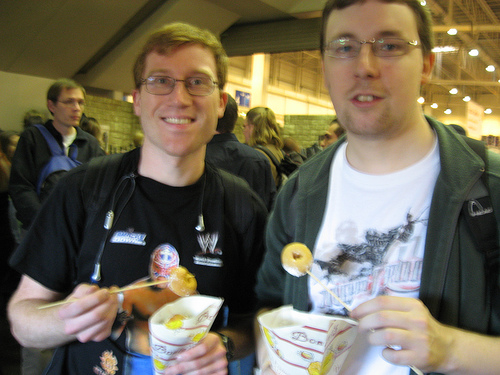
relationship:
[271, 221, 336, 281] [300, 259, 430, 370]
treat on stick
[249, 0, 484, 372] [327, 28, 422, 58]
man wearing eyeglasses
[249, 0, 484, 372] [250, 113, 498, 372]
man wearing jacket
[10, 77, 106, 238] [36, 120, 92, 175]
man carrying backpack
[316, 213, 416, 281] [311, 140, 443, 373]
design on shirt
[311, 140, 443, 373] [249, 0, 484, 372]
shirt on man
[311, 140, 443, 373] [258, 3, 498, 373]
shirt on man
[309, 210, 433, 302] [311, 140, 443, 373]
design on shirt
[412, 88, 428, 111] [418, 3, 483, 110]
light on ceiling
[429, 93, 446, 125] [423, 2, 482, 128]
light on ceiling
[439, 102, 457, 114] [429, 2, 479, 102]
light on ceiling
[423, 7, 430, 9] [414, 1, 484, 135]
light on ceiling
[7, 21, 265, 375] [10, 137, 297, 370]
boys wearing shirt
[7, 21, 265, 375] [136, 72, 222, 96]
boys with eyeglass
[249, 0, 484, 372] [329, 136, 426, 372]
man wearing shirt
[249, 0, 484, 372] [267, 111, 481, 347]
man wearing jacket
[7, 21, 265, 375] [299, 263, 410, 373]
boys holding stick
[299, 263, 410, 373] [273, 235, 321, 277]
stick with donut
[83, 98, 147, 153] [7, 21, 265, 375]
wall behind boys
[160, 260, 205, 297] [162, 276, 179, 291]
donut with sugar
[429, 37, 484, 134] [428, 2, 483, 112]
lights hanging from ceiling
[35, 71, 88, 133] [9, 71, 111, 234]
head of man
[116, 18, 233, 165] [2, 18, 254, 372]
head of man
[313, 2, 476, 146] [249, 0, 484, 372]
head of man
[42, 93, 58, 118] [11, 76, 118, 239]
ear of man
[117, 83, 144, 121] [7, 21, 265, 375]
ear of boys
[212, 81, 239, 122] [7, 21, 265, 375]
ear of boys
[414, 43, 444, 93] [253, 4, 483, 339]
ear of man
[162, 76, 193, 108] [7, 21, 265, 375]
nose of boys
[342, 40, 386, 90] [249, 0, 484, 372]
nose of man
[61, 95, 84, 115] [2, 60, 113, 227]
nose of man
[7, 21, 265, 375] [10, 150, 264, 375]
boys wearing shirt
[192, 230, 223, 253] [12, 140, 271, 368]
w on shirt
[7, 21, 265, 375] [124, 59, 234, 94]
boys wearing eyeglass